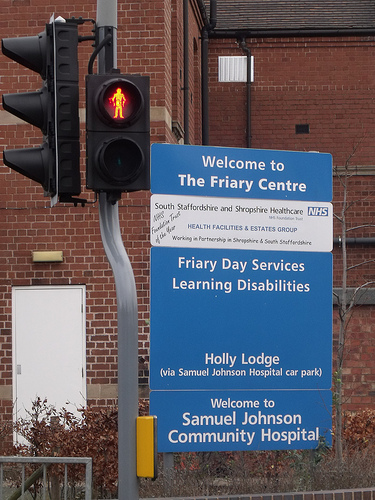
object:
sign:
[150, 144, 333, 455]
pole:
[99, 189, 139, 500]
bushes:
[10, 392, 373, 499]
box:
[135, 413, 157, 479]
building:
[2, 2, 373, 460]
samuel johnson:
[179, 412, 306, 427]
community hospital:
[167, 426, 320, 443]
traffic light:
[88, 130, 150, 189]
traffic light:
[0, 9, 84, 79]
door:
[11, 284, 86, 444]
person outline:
[110, 88, 125, 117]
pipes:
[78, 35, 112, 76]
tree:
[325, 146, 374, 470]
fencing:
[4, 454, 371, 499]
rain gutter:
[200, 30, 208, 147]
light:
[99, 81, 139, 118]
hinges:
[81, 301, 88, 381]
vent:
[218, 55, 255, 85]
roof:
[200, 3, 374, 36]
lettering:
[160, 369, 325, 397]